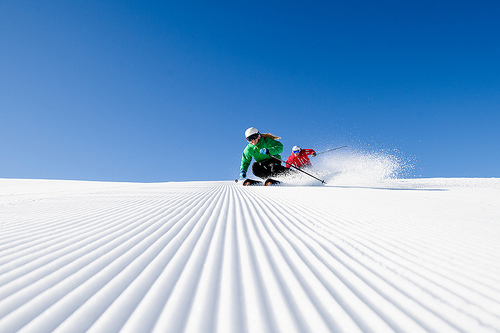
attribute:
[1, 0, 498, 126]
sky — bright, blue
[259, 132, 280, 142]
hair — long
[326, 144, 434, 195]
dust — snow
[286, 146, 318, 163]
jacket — red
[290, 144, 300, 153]
helmet — white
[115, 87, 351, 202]
skiing —  skiing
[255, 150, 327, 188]
skipole — ski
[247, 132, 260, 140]
glasses — sun, black, sketting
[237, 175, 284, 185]
skis — black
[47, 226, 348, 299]
snow — thick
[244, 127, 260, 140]
helmet — white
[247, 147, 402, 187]
snow — kicked up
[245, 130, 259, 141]
sunglasses — dark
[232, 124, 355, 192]
people — skiing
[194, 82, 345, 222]
woman — brown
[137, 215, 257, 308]
lines — neat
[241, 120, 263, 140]
helmet — white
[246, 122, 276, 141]
hair — long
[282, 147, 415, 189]
snow — flurry